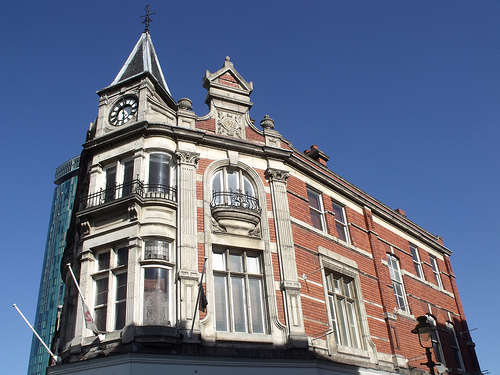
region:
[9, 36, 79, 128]
the sky is clear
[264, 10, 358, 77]
the sky is clear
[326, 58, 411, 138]
the sky is clear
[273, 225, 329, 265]
a red bricked wall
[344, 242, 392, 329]
a red bricked wall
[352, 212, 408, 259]
a red bricked wall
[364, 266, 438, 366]
a red bricked wall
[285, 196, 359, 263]
a red bricked wall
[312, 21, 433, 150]
clear sky without any clouds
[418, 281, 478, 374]
shadow cast on the side of a building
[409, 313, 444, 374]
turned off light post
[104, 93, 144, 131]
white and black clock face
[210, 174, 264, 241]
stone balcony on a building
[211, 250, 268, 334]
windows on the side of a building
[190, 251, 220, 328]
limp flag on the side of a building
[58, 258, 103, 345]
white flag pole on the side of a building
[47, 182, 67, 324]
tall building with many windows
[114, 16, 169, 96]
white gabled clock tower roof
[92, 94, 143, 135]
clock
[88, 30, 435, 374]
brown and white building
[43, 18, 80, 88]
white clouds in blue sky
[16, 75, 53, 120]
white clouds in blue sky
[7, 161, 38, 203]
white clouds in blue sky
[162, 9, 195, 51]
white clouds in blue sky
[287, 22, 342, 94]
white clouds in blue sky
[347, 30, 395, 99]
white clouds in blue sky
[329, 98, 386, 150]
white clouds in blue sky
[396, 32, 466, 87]
white clouds in blue sky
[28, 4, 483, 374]
Tall brick building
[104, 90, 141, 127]
Clock on the top of a building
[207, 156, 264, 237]
Window balcony on building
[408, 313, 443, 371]
Old style street lamp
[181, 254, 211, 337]
Flag hanging off of post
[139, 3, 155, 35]
Decorative spire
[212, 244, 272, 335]
Long window panes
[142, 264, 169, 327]
window pane with fancy painting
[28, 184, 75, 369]
Tall glass building in background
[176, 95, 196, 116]
Concrete sculptures on edges of building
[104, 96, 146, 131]
Black and white clock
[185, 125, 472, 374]
Red and white brick building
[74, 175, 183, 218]
Black railing on balcony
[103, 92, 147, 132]
Black hands on white clock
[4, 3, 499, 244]
Clear, blue sky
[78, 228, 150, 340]
Large white window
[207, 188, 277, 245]
Black railing on second balcony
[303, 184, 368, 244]
Set of two windows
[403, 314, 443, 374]
Black metal street lamp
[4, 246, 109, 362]
Two white flag holders